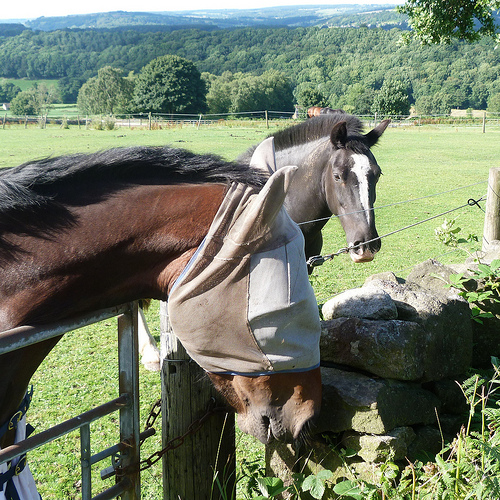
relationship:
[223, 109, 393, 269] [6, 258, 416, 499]
horse is standing next to fence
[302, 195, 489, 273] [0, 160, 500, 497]
wire is attached to fence next to horse